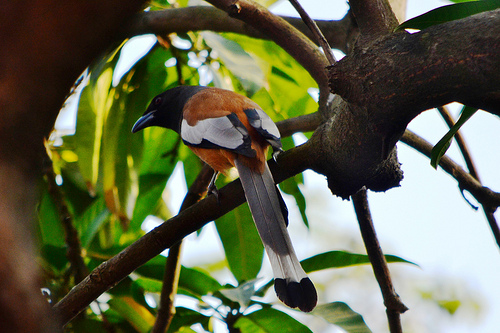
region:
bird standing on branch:
[124, 79, 289, 223]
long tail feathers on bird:
[228, 162, 325, 316]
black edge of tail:
[265, 265, 325, 317]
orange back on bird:
[191, 85, 252, 122]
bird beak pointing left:
[124, 104, 170, 144]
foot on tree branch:
[168, 181, 238, 241]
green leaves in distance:
[185, 227, 258, 329]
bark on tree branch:
[383, 42, 467, 93]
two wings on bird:
[188, 108, 284, 164]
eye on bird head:
[147, 91, 175, 110]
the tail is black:
[213, 254, 348, 322]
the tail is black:
[277, 284, 314, 319]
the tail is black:
[281, 253, 361, 314]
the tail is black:
[221, 232, 317, 287]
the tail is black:
[251, 280, 301, 322]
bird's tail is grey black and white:
[226, 168, 326, 318]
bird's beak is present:
[120, 111, 167, 151]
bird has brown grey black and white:
[162, 80, 269, 160]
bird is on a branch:
[109, 81, 410, 268]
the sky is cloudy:
[392, 183, 464, 278]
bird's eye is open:
[150, 84, 185, 130]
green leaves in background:
[81, 80, 202, 245]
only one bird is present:
[83, 68, 359, 268]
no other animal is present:
[54, 40, 424, 272]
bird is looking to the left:
[106, 74, 373, 315]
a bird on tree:
[132, 58, 272, 210]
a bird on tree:
[128, 63, 328, 308]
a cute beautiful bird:
[120, 87, 352, 326]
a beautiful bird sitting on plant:
[120, 77, 352, 312]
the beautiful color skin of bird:
[196, 98, 258, 140]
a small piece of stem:
[341, 198, 426, 331]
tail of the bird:
[219, 150, 317, 311]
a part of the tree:
[4, 5, 122, 185]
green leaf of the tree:
[205, 199, 284, 302]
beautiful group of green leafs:
[62, 73, 312, 300]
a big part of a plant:
[292, 29, 430, 205]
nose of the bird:
[126, 100, 201, 141]